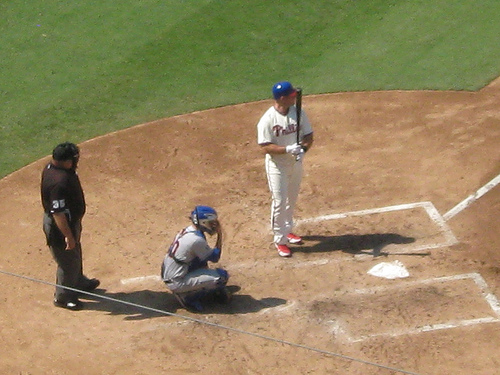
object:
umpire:
[38, 141, 103, 311]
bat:
[295, 86, 302, 163]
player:
[158, 205, 234, 313]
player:
[252, 82, 314, 258]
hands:
[285, 141, 304, 156]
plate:
[366, 259, 411, 279]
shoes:
[274, 240, 293, 257]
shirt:
[40, 164, 87, 221]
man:
[253, 79, 314, 259]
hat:
[271, 81, 298, 101]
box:
[315, 269, 497, 348]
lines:
[270, 203, 417, 227]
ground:
[1, 318, 125, 372]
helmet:
[188, 204, 218, 236]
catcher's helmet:
[188, 204, 220, 236]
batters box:
[329, 258, 497, 337]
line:
[439, 171, 499, 223]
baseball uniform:
[157, 205, 229, 309]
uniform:
[159, 205, 229, 309]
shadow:
[296, 231, 394, 254]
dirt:
[311, 299, 328, 315]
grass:
[3, 2, 66, 96]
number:
[52, 200, 60, 210]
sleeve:
[46, 184, 71, 216]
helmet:
[272, 80, 297, 100]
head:
[272, 81, 298, 107]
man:
[38, 138, 100, 309]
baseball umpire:
[36, 142, 101, 311]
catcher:
[157, 205, 230, 310]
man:
[158, 204, 231, 308]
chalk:
[302, 202, 415, 222]